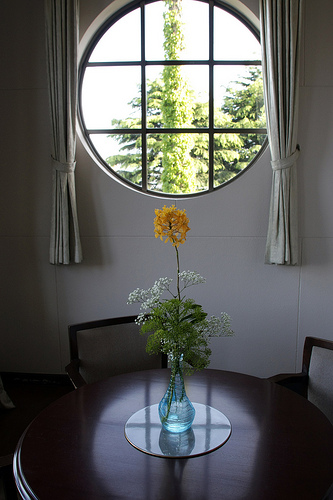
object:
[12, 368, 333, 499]
table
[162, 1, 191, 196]
tree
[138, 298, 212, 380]
plant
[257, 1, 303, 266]
curtain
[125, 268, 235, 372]
baby breath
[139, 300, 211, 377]
filler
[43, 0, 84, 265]
curtain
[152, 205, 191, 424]
flower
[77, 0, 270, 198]
window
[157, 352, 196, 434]
flower case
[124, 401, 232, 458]
mirror plate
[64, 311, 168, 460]
chair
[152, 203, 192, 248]
yellow bloom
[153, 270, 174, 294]
flower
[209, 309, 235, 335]
flower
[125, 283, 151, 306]
flower